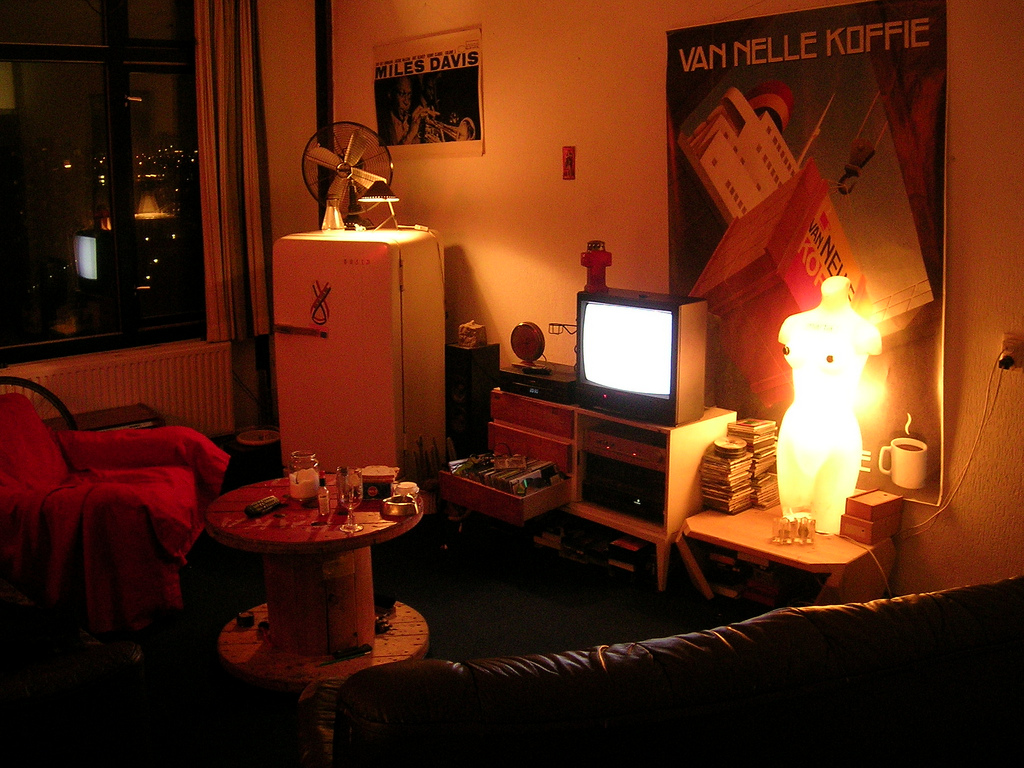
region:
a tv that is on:
[576, 298, 679, 404]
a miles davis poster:
[367, 35, 495, 150]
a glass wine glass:
[339, 468, 366, 530]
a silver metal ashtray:
[378, 496, 414, 515]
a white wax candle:
[285, 445, 324, 494]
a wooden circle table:
[198, 456, 436, 681]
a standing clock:
[506, 317, 554, 368]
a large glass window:
[4, 3, 221, 367]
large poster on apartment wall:
[677, 12, 930, 497]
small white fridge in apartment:
[296, 224, 453, 463]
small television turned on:
[573, 279, 707, 419]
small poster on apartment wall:
[374, 35, 483, 159]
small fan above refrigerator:
[296, 133, 401, 235]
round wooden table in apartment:
[210, 473, 423, 689]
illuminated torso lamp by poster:
[751, 262, 887, 534]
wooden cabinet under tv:
[497, 391, 725, 566]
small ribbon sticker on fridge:
[298, 265, 356, 339]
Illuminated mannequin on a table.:
[780, 274, 885, 547]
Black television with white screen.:
[574, 284, 710, 425]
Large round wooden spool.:
[207, 471, 435, 683]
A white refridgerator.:
[267, 227, 448, 491]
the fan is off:
[273, 102, 429, 261]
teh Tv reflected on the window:
[50, 213, 128, 304]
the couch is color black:
[337, 568, 1019, 765]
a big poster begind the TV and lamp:
[645, 1, 978, 531]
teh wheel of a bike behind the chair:
[0, 352, 93, 461]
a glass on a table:
[327, 457, 371, 540]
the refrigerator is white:
[253, 217, 467, 478]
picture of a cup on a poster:
[862, 371, 957, 519]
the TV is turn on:
[563, 270, 717, 433]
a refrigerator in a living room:
[257, 225, 463, 490]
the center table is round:
[189, 434, 450, 697]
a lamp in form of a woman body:
[753, 258, 890, 541]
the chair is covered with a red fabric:
[0, 373, 248, 658]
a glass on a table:
[321, 460, 370, 534]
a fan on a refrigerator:
[264, 111, 430, 261]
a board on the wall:
[366, 13, 498, 180]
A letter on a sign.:
[670, 33, 697, 82]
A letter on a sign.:
[689, 46, 706, 69]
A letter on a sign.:
[702, 39, 723, 71]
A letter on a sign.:
[733, 40, 749, 61]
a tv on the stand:
[594, 296, 671, 470]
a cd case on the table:
[707, 467, 742, 497]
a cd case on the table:
[716, 423, 739, 462]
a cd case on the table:
[743, 439, 786, 469]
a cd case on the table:
[726, 443, 777, 501]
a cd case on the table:
[759, 369, 782, 483]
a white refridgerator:
[263, 219, 437, 464]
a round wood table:
[215, 450, 430, 676]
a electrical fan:
[294, 114, 400, 225]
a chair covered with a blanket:
[0, 377, 222, 621]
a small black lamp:
[364, 168, 428, 246]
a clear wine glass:
[333, 468, 376, 535]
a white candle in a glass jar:
[276, 444, 318, 506]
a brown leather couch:
[327, 586, 1007, 757]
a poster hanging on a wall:
[376, 13, 493, 157]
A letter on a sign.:
[698, 35, 725, 71]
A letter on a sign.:
[729, 35, 750, 65]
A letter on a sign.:
[759, 38, 778, 61]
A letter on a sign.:
[767, 26, 805, 59]